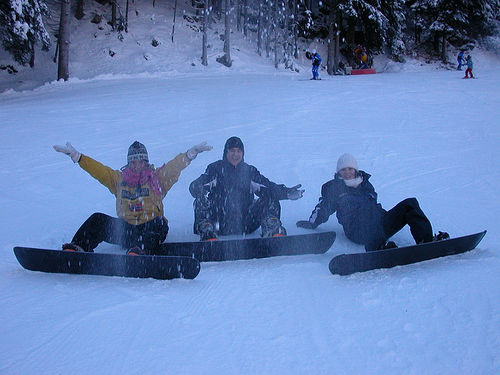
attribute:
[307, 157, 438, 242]
woman — smiling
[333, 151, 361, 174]
cap — white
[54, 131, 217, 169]
gloves — white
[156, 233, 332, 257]
snowboard — black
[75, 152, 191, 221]
sweatshirt — yellow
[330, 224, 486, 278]
snowboard — black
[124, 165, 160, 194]
scarf — fuchsia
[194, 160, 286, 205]
coat — black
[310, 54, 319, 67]
uniform — blue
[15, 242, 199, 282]
snowboard — black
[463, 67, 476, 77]
pants — red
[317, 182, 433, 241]
suit — black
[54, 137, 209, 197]
arms — raised